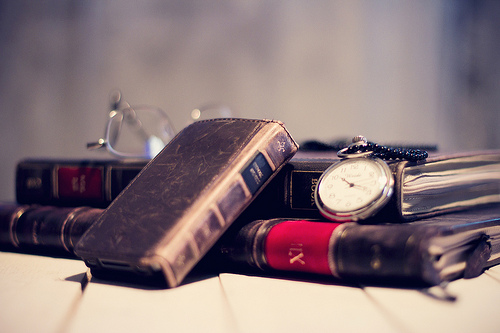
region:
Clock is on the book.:
[295, 123, 415, 241]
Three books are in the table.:
[181, 128, 375, 330]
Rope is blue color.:
[348, 114, 435, 181]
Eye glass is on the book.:
[76, 85, 322, 198]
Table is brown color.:
[38, 260, 178, 332]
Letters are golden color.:
[17, 169, 359, 276]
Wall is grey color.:
[217, 13, 447, 86]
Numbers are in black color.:
[316, 160, 384, 211]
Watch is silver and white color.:
[316, 143, 398, 223]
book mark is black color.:
[453, 234, 495, 289]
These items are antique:
[13, 26, 495, 272]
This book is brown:
[102, 104, 267, 315]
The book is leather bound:
[97, 110, 242, 266]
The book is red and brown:
[249, 205, 488, 299]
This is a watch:
[324, 131, 476, 248]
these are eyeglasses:
[72, 80, 252, 161]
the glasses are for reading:
[64, 86, 211, 168]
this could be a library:
[51, 104, 464, 314]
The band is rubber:
[332, 118, 460, 179]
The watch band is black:
[332, 122, 464, 202]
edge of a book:
[154, 263, 180, 283]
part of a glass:
[344, 184, 364, 209]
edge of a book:
[287, 238, 327, 275]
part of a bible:
[152, 253, 202, 297]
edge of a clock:
[363, 192, 374, 203]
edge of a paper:
[203, 273, 248, 313]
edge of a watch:
[366, 195, 383, 213]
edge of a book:
[351, 240, 381, 266]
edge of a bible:
[184, 224, 244, 275]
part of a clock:
[377, 150, 392, 211]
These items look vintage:
[29, 41, 464, 316]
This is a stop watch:
[324, 139, 411, 249]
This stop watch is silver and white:
[322, 144, 422, 239]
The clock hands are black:
[309, 162, 438, 259]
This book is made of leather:
[257, 214, 469, 294]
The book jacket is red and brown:
[254, 218, 461, 313]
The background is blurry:
[80, 12, 447, 178]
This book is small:
[75, 110, 255, 292]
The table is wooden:
[97, 268, 271, 332]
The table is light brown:
[160, 265, 267, 312]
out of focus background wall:
[1, 0, 498, 203]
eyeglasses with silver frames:
[83, 85, 239, 158]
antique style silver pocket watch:
[313, 133, 394, 222]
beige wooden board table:
[0, 247, 499, 332]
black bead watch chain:
[300, 135, 438, 160]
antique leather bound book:
[13, 149, 499, 220]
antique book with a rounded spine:
[0, 195, 499, 293]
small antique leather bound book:
[73, 116, 298, 291]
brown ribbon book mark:
[461, 230, 493, 280]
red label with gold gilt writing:
[51, 161, 114, 207]